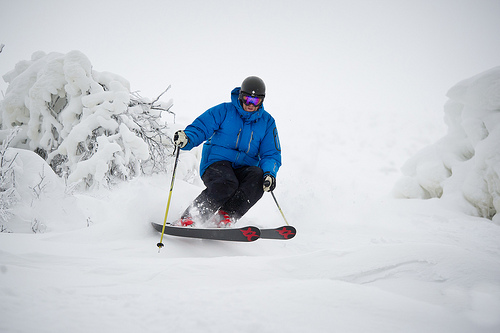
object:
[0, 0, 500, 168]
sky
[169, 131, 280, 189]
hands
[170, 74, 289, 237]
man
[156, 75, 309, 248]
man's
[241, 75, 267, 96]
black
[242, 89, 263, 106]
goggles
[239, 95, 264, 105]
black framed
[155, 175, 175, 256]
yellow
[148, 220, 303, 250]
skis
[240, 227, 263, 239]
red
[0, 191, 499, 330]
ground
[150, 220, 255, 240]
black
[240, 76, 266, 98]
black helmet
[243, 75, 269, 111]
head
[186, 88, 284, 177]
blue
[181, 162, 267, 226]
black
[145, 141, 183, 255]
ski pole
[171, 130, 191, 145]
hand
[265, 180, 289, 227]
ski pole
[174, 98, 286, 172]
coat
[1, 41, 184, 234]
bush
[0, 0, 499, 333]
snow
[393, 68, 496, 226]
bush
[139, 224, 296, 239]
ski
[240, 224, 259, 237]
design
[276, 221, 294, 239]
design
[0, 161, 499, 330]
ski slope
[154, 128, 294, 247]
limbs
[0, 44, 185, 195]
tree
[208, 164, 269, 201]
knees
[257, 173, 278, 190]
left hand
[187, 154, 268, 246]
pants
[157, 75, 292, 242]
person